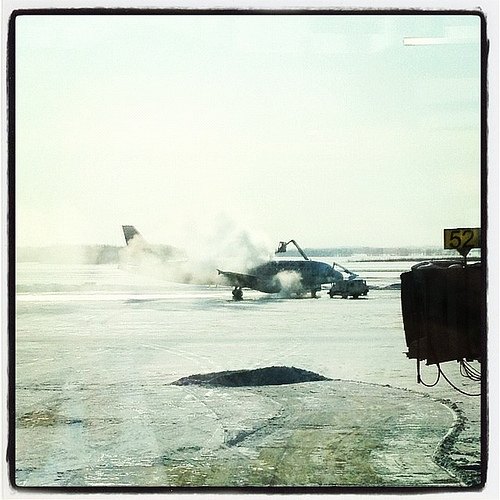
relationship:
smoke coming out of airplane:
[122, 232, 272, 278] [122, 220, 364, 297]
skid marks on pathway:
[43, 355, 170, 487] [15, 264, 481, 486]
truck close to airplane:
[333, 272, 372, 328] [230, 239, 334, 319]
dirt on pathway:
[172, 365, 328, 386] [253, 384, 446, 477]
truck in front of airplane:
[327, 279, 371, 299] [210, 256, 340, 297]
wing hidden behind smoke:
[120, 222, 233, 294] [112, 201, 273, 310]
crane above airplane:
[272, 234, 312, 263] [120, 223, 345, 303]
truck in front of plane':
[327, 279, 371, 299] [96, 218, 382, 303]